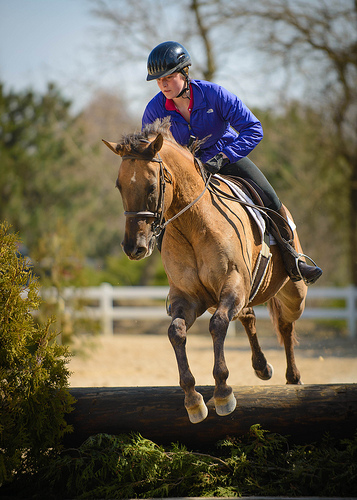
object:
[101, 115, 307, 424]
horse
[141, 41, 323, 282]
rider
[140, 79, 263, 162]
jacket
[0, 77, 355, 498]
log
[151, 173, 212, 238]
bridle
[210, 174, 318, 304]
stirrup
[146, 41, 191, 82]
helmet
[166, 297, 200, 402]
dirt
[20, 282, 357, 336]
fence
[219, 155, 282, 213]
pants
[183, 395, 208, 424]
hooves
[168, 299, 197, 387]
legs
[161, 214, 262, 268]
fur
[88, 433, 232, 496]
foilage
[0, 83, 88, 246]
leaves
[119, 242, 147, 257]
nose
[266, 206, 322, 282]
boot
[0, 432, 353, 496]
greenery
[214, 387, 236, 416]
hoof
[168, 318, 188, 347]
knees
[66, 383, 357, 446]
tree